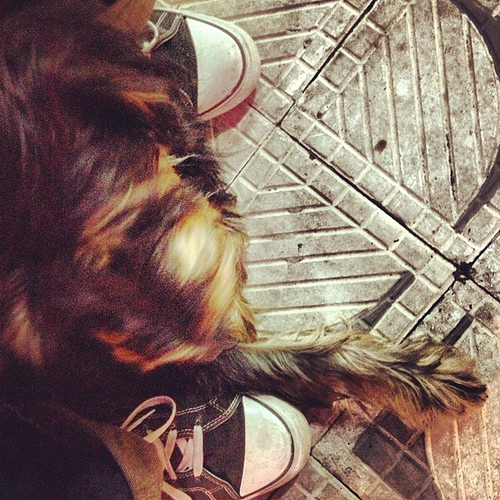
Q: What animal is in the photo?
A: Dog.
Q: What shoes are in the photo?
A: Sneakers.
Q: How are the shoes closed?
A: With shoelaces.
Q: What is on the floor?
A: Vinyl tiles.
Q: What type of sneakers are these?
A: Chuck taylor.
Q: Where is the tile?
A: On the floor.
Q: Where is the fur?
A: On the dog.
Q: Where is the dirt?
A: On the floor.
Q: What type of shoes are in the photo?
A: Sneakers.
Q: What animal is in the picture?
A: A dog.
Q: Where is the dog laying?
A: At a human's feet.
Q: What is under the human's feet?
A: Tile flooring.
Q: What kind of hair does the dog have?
A: Shaggy.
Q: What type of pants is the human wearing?
A: Blue Jeans.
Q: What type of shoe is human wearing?
A: Chuck sneakers.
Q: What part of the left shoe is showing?
A: The toe.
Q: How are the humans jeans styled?
A: Cuffed.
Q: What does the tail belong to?
A: Dog.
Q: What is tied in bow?
A: Shoes.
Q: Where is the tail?
A: On dog.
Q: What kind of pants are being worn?
A: Jeans.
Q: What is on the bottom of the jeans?
A: Cuff.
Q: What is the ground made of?
A: Cement.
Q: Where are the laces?
A: In shoes.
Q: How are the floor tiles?
A: Dirty.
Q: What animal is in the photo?
A: Dog.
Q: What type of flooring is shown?
A: Vinyl tiles.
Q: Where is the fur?
A: On the dog.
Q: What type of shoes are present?
A: Sneakers.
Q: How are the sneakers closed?
A: Shoe laces.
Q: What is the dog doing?
A: Laying down.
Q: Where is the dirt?
A: On the floor.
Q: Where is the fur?
A: On the dog.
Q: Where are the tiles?
A: On the floor.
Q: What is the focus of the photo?
A: Shoes.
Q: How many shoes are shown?
A: Two.